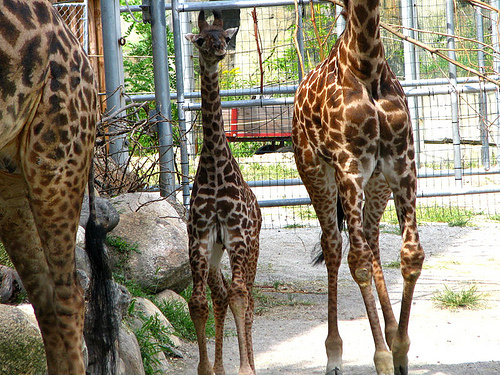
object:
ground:
[173, 220, 500, 374]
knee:
[227, 284, 250, 307]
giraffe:
[185, 8, 263, 374]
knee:
[189, 295, 209, 319]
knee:
[211, 292, 231, 306]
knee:
[401, 245, 424, 283]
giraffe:
[291, 1, 425, 374]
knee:
[348, 250, 376, 282]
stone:
[102, 192, 193, 293]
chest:
[196, 178, 243, 243]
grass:
[430, 284, 487, 310]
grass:
[387, 256, 403, 270]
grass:
[255, 292, 313, 316]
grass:
[259, 280, 289, 293]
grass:
[445, 217, 469, 228]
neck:
[337, 2, 390, 78]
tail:
[83, 158, 128, 373]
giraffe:
[0, 0, 121, 374]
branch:
[379, 21, 500, 138]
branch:
[102, 169, 196, 192]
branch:
[117, 117, 177, 194]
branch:
[98, 103, 152, 129]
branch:
[100, 137, 113, 195]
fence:
[53, 2, 499, 229]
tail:
[310, 235, 327, 271]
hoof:
[325, 362, 345, 375]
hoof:
[394, 364, 409, 374]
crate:
[219, 104, 298, 139]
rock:
[124, 296, 185, 343]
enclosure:
[0, 2, 500, 374]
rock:
[156, 289, 190, 319]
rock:
[120, 325, 145, 373]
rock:
[1, 303, 48, 373]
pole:
[100, 1, 129, 169]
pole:
[148, 2, 177, 200]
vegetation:
[148, 297, 196, 343]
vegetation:
[140, 317, 178, 374]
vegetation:
[107, 233, 146, 295]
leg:
[25, 94, 91, 370]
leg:
[0, 180, 63, 373]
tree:
[120, 2, 180, 156]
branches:
[92, 98, 156, 121]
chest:
[345, 95, 410, 162]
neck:
[199, 63, 228, 149]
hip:
[27, 3, 98, 162]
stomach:
[1, 120, 27, 152]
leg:
[225, 234, 253, 374]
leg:
[189, 233, 209, 373]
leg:
[207, 269, 230, 374]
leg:
[307, 183, 346, 373]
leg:
[336, 181, 396, 374]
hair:
[86, 217, 122, 374]